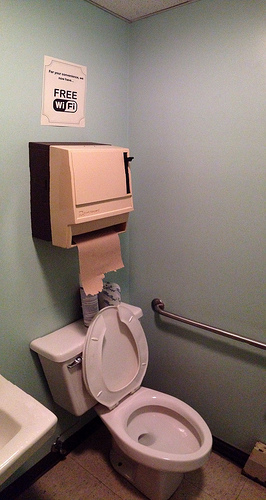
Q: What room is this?
A: Bathroom.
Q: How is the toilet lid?
A: Raised.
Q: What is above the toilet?
A: Towel dispenser.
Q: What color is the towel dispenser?
A: Tan.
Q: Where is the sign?
A: On the wall.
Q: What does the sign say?
A: Free WIFI.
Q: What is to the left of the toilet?
A: A sink.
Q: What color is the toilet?
A: White.